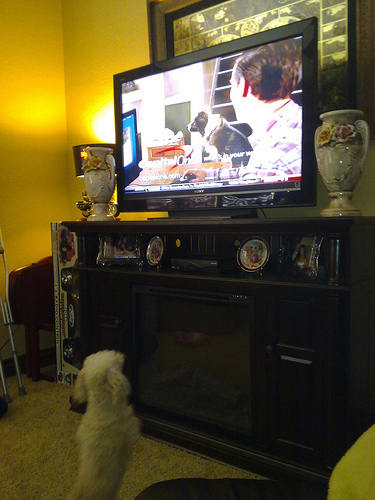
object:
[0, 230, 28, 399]
crutches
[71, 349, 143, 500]
dog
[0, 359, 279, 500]
carpet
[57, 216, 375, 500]
entertainment center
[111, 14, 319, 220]
television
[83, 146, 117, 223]
vase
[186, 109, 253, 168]
dog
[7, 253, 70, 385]
chair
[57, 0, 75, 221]
corner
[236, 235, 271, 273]
plate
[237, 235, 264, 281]
shelf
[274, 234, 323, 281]
frame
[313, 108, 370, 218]
vase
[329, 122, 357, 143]
rose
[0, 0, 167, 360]
wall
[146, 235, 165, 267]
china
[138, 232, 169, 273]
shelf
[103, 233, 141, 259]
photo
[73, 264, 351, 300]
shelf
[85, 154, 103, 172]
flower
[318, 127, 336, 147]
flower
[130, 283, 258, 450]
fireplace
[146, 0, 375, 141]
picture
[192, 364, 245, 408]
logs